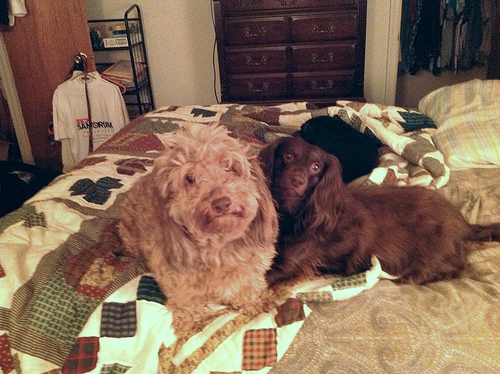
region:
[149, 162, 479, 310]
two dogs on a bed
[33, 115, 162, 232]
a quilt on the bed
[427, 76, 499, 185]
a pillow on the bed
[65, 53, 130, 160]
shirts on the door knob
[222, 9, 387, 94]
the dresser has drawers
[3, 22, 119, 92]
the door is open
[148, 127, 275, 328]
the dog is fluffy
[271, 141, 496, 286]
the dog has brown hair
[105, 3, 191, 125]
metal stand behind the door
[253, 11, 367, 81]
the dresser is dark wood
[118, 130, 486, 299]
these are two dogs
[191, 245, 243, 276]
the fur is white in color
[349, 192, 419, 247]
the fur is brown in color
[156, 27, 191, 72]
this is the wall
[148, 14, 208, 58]
the wall is white in color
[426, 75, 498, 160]
this is a pillow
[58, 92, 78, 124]
the t-shirt is white in color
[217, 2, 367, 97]
these are some drawers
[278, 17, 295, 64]
the drawers are brown in color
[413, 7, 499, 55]
these are some clothes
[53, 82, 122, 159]
A white tshirt hanging from the doorknob.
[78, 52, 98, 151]
Long brown belt hanging.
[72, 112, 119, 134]
Colorful logo on white tshirt.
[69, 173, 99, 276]
Plaid colored quilt on bed.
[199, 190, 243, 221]
Brownish red nose on dog.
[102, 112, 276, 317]
Blondish colored dog on bed.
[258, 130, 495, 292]
Brown long haired dog on bed.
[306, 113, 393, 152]
Black knitted sweater on bed.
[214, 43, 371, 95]
Burgandy elm wood dresser.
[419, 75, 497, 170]
Multicolored pillow case on pillow.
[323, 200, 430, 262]
the fur is brown in color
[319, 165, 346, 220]
the ear is long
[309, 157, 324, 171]
this is the eye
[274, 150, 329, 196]
the dog is staring at the camera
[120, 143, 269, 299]
the dog is cream in color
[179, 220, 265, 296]
the dog is fury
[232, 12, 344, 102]
the cupboards are closed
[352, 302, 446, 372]
this is a duvee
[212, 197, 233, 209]
this is the nose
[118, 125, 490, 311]
two dogs laying on a bed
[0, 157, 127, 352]
a colorful quilt on a bed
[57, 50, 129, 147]
a white shirt on a hanger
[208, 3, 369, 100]
a wooden dresser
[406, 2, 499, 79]
a selection of clothes in a closet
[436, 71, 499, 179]
a pillow with rainbow lines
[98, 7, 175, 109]
a black metal shelf unit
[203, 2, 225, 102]
a black wire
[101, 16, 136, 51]
a white box on a shelf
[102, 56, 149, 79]
a wood frame on a shelf